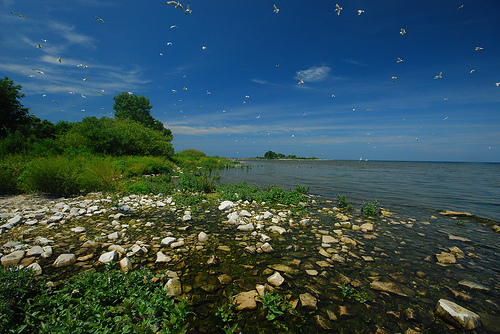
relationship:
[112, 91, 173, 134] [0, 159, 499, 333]
tree next to water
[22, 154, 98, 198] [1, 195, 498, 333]
bush near rocks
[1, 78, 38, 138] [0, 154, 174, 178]
bushy tree over land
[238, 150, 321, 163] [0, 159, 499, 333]
island over water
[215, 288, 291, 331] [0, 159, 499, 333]
plants inside of water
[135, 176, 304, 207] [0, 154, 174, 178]
plants near land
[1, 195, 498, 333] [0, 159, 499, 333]
rocks inside of water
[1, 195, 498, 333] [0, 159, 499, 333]
rocks under water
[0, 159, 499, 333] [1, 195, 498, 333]
water around rocks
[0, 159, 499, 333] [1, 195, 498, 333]
water over rocks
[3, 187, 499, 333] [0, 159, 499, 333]
plants and rocks inside of water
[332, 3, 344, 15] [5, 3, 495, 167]
bird flying in sky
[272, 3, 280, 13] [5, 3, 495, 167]
bird flying in sky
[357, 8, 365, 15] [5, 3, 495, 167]
bird flying in sky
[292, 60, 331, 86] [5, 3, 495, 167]
cloud above sky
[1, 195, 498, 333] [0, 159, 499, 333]
rocks inside water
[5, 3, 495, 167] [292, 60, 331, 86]
sky has cloud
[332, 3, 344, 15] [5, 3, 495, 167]
bird under sky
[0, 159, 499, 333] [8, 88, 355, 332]
water next to scenery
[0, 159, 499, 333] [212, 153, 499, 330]
rocks in water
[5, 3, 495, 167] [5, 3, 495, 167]
birds in sky